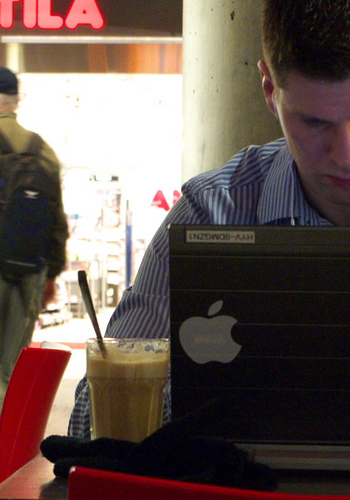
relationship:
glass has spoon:
[80, 330, 169, 447] [73, 268, 121, 360]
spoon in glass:
[73, 268, 121, 360] [80, 330, 169, 447]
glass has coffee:
[80, 330, 169, 447] [86, 349, 169, 443]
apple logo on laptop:
[175, 295, 248, 372] [162, 217, 349, 482]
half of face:
[252, 59, 350, 209] [249, 56, 346, 214]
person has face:
[65, 2, 349, 451] [249, 56, 346, 214]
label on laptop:
[178, 227, 263, 252] [162, 217, 349, 482]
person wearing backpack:
[1, 65, 74, 418] [1, 120, 67, 291]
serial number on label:
[188, 230, 255, 244] [178, 227, 263, 252]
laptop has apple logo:
[162, 217, 349, 482] [175, 295, 248, 372]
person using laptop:
[65, 2, 349, 451] [162, 217, 349, 482]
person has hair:
[65, 2, 349, 451] [256, 2, 349, 97]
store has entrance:
[1, 2, 186, 349] [19, 72, 187, 346]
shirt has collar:
[65, 133, 349, 444] [253, 140, 335, 229]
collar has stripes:
[253, 140, 335, 229] [277, 165, 293, 207]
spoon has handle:
[73, 268, 121, 360] [73, 266, 118, 359]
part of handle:
[71, 267, 102, 303] [73, 266, 118, 359]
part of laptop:
[171, 254, 216, 292] [162, 217, 349, 482]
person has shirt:
[65, 2, 349, 451] [65, 133, 349, 444]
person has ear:
[65, 2, 349, 451] [249, 54, 286, 124]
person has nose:
[65, 2, 349, 451] [324, 120, 350, 178]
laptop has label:
[162, 217, 349, 482] [178, 227, 263, 252]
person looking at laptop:
[65, 2, 349, 451] [162, 217, 349, 482]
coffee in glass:
[86, 349, 172, 443] [80, 330, 169, 447]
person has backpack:
[1, 65, 74, 418] [1, 120, 67, 291]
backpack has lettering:
[1, 120, 67, 291] [24, 184, 43, 201]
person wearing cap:
[1, 65, 74, 418] [1, 65, 24, 100]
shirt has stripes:
[65, 133, 349, 444] [277, 165, 293, 207]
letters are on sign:
[1, 3, 114, 35] [1, 1, 186, 41]